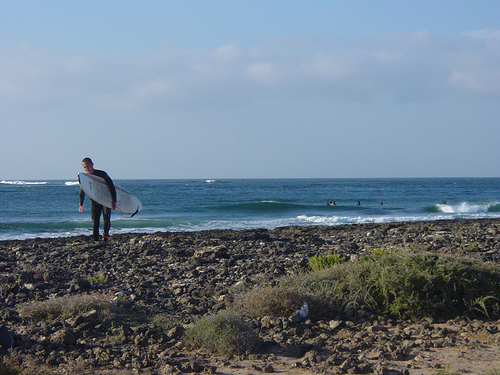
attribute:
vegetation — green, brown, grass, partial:
[235, 248, 500, 317]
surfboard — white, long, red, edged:
[75, 170, 144, 214]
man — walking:
[75, 151, 119, 240]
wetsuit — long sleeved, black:
[76, 170, 117, 239]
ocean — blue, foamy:
[1, 177, 500, 244]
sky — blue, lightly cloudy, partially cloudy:
[1, 2, 499, 181]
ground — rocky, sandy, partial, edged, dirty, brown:
[1, 217, 498, 375]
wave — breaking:
[433, 202, 489, 215]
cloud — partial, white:
[285, 33, 499, 119]